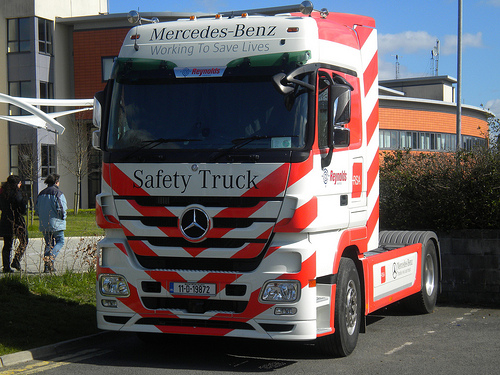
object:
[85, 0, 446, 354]
truck cab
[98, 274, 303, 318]
headlights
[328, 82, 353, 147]
side mirror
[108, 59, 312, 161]
windshield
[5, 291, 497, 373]
parking lot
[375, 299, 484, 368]
faded markings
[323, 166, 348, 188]
reynolds logo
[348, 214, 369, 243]
stepup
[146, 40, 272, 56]
lettering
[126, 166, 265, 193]
safety truck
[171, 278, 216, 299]
license plate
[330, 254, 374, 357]
tire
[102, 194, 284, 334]
grill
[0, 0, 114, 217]
building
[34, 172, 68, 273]
girl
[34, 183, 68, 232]
blue coat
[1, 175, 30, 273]
girl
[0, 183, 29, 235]
black coat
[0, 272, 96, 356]
grass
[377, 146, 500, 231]
bushes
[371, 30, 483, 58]
clouds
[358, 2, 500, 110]
sky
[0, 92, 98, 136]
white overhang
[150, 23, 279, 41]
logo